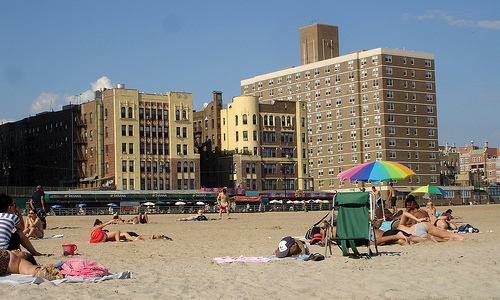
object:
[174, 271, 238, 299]
sand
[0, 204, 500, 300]
beach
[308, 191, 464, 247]
family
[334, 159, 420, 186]
umbrella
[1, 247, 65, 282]
woman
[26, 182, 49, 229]
man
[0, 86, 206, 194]
building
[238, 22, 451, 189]
apartment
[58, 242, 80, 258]
pail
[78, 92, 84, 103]
steam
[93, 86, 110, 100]
chimney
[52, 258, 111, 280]
blanket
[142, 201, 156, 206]
umbrella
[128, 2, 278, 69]
sky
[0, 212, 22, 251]
shirt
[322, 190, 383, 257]
chair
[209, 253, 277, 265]
towel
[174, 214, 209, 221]
person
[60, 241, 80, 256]
bucket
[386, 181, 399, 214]
people